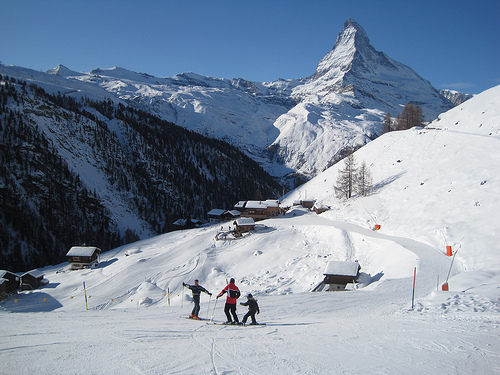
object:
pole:
[411, 267, 417, 309]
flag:
[410, 267, 416, 308]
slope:
[279, 129, 498, 272]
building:
[66, 246, 102, 270]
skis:
[179, 316, 210, 322]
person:
[215, 277, 241, 325]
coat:
[216, 282, 241, 304]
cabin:
[322, 260, 361, 284]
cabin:
[233, 218, 256, 233]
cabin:
[244, 200, 268, 215]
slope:
[0, 290, 500, 375]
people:
[181, 278, 212, 320]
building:
[20, 269, 45, 290]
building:
[0, 269, 22, 293]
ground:
[0, 203, 500, 375]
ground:
[400, 79, 424, 100]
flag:
[446, 246, 453, 257]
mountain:
[303, 18, 455, 113]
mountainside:
[0, 84, 500, 312]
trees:
[330, 145, 357, 200]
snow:
[195, 106, 202, 111]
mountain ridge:
[172, 71, 192, 78]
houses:
[302, 199, 313, 208]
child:
[239, 292, 260, 324]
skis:
[246, 322, 267, 326]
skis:
[206, 322, 239, 326]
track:
[210, 336, 220, 374]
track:
[431, 340, 449, 352]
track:
[478, 308, 486, 312]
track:
[468, 318, 472, 321]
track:
[441, 307, 447, 310]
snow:
[0, 84, 499, 375]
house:
[267, 201, 279, 217]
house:
[207, 208, 228, 223]